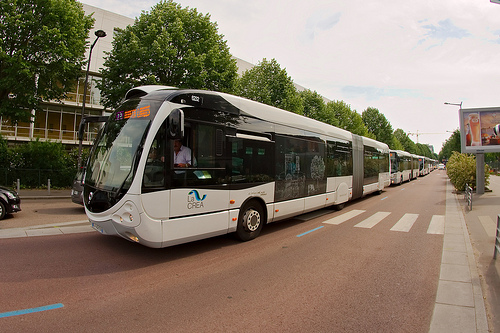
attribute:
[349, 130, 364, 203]
accordian panel — flexible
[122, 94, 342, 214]
bus — safely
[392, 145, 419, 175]
bus — safely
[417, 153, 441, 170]
bus — safely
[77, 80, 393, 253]
bus — new, double length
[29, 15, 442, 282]
buses — good drivers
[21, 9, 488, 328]
buses — fleet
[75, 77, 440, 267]
buses — new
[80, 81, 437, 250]
buses — white, modern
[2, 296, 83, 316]
line — Blue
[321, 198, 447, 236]
crosswalk — white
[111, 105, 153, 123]
bus destination — bus 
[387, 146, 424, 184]
bus — new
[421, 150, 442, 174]
bus — new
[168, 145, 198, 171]
shirt — white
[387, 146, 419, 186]
bus — double length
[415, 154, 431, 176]
bus — double length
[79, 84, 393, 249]
buses — sleek 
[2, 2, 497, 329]
city — big 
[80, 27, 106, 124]
street light — tall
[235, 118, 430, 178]
passengers — many 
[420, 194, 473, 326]
sidewalk — middle 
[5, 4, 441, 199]
trees — string  